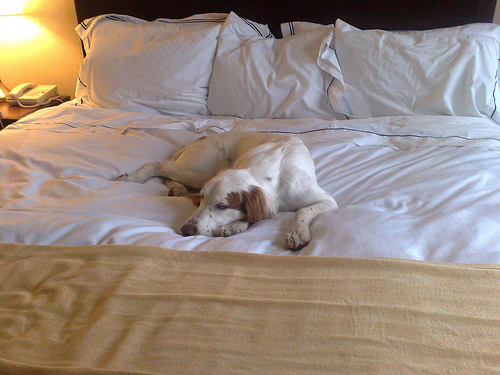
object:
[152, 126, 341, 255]
dog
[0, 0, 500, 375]
bed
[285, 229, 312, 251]
paw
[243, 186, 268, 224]
ear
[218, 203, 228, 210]
eye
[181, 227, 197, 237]
nose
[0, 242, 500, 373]
blanket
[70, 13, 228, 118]
pillow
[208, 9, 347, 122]
pillow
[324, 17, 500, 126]
pillow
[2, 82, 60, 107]
phone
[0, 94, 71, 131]
nightstand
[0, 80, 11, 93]
lamp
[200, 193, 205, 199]
eye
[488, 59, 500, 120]
stripe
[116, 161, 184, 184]
leg